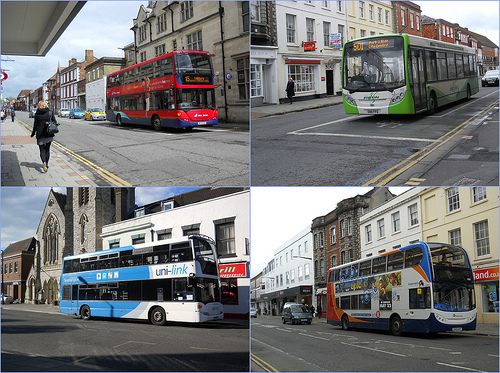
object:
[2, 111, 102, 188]
sidewalk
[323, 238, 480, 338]
bus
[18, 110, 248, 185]
road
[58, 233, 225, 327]
bus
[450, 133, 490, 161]
water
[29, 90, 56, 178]
woman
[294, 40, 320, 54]
sign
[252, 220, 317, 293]
building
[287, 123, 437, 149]
line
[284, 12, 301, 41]
window